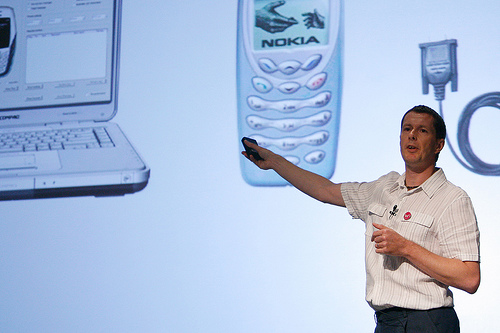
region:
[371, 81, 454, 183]
head of a man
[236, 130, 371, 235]
arm of the man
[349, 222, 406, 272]
hand of the man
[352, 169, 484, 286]
shirt on the man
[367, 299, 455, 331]
black pants on man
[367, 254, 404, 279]
shadow on the shirt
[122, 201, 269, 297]
white background of photo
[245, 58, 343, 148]
buttons on the phone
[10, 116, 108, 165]
keys on the keyboard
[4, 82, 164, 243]
picture of a laptop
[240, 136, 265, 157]
Remote in a man's hand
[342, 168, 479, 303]
White striped shirt on a man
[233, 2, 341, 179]
Large image of a cell phone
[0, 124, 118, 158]
Keyboard on laptop computer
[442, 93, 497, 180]
Coiled cable on a wall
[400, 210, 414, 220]
Red patch on a shirt pocket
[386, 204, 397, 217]
Microphone clipped to a shirt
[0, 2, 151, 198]
Image of a laptop computer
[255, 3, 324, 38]
Hands image on a screen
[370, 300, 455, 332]
Black pants on a man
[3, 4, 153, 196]
light colored open laptop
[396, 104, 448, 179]
one man with short dark hair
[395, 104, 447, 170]
one Caucasian man with partially open mouth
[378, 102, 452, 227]
one man wearing round red button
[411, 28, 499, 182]
gray wound up computer cable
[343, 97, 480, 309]
man wearing light colored striped top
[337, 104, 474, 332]
man wearing black dress pants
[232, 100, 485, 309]
one man with right hand outstretched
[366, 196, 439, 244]
double light colored shirt pockets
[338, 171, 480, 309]
short sleeved white shirt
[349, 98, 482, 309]
Man wearing white shirt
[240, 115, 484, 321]
Man holding a remote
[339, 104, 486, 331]
Man wearing white shirt and blue pants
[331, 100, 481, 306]
Man wearing mini microphone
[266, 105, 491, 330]
Man pointing behind him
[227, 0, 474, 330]
Man using a projector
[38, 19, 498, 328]
Man giving a presentation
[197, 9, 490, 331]
Man pointing at a wall behind him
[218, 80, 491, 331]
Man giving a speech with a projector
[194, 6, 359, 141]
Large image of a Nokia phone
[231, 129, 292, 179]
A man's hand holding a phone.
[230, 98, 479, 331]
A man standing and holding a phone.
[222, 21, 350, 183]
large graphic of a nokia cell phone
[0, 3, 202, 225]
large graphic of a silver laptop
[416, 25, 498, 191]
large graphic of an electric cord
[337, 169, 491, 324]
white striped shirt with pockets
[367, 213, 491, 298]
caucasian male forearm with thumbs up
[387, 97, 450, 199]
caucasian male's head with open mouth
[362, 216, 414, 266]
hand with relaxed thumbs up gesture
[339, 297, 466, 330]
upper half of caucasian male's pants